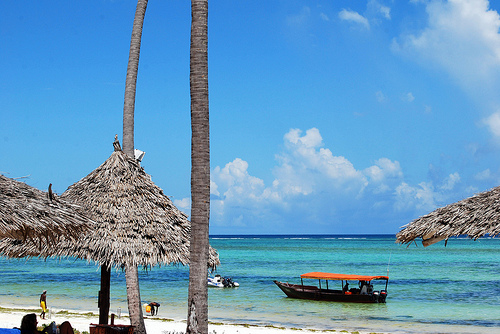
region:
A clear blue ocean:
[0, 233, 494, 333]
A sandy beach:
[1, 308, 360, 333]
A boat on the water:
[273, 268, 392, 303]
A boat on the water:
[207, 270, 238, 285]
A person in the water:
[143, 299, 160, 316]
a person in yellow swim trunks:
[36, 285, 53, 316]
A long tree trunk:
[183, 3, 210, 331]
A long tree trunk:
[120, 0, 151, 333]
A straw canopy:
[58, 144, 225, 274]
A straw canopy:
[395, 185, 498, 253]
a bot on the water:
[253, 263, 399, 330]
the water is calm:
[243, 235, 281, 286]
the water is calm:
[266, 235, 339, 265]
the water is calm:
[311, 235, 408, 279]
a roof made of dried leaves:
[27, 128, 211, 317]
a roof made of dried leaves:
[71, 158, 183, 268]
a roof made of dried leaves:
[3, 168, 74, 236]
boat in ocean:
[275, 261, 395, 315]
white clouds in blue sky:
[7, 3, 62, 47]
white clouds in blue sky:
[2, 63, 44, 107]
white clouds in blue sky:
[41, 51, 128, 115]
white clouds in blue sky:
[5, 108, 63, 148]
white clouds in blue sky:
[141, 99, 198, 144]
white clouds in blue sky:
[234, 16, 288, 66]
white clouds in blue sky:
[235, 81, 295, 132]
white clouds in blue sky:
[244, 153, 322, 207]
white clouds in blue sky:
[277, 112, 357, 173]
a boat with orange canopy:
[274, 250, 436, 312]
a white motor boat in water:
[196, 269, 241, 292]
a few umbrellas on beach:
[4, 131, 214, 267]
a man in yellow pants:
[27, 280, 69, 325]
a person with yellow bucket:
[145, 292, 171, 323]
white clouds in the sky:
[206, 122, 431, 241]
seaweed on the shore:
[20, 299, 326, 332]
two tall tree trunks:
[107, 8, 237, 333]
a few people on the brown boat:
[332, 274, 375, 305]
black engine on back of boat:
[218, 273, 234, 293]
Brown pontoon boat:
[272, 270, 391, 302]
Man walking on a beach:
[37, 286, 49, 318]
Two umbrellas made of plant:
[0, 150, 220, 271]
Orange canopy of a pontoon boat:
[301, 268, 391, 283]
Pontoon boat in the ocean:
[274, 268, 390, 304]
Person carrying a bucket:
[143, 300, 161, 319]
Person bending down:
[145, 299, 159, 317]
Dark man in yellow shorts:
[38, 288, 49, 321]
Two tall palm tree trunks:
[119, 0, 211, 333]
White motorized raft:
[206, 274, 241, 290]